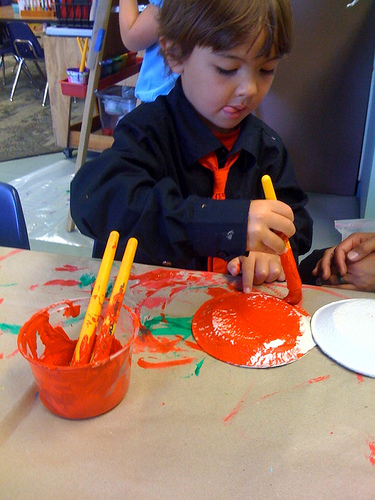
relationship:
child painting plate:
[69, 0, 314, 297] [191, 293, 316, 369]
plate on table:
[309, 296, 374, 381] [0, 245, 374, 498]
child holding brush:
[69, 0, 314, 297] [258, 173, 302, 299]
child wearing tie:
[69, 0, 314, 297] [198, 150, 241, 274]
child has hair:
[69, 0, 314, 297] [159, 0, 293, 81]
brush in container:
[73, 36, 89, 71] [67, 66, 90, 83]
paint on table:
[18, 297, 139, 420] [0, 245, 374, 498]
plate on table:
[191, 293, 316, 369] [0, 245, 374, 498]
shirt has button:
[70, 76, 314, 268] [214, 249, 229, 260]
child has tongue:
[69, 0, 314, 297] [222, 104, 236, 116]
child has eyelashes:
[69, 0, 314, 297] [214, 64, 238, 75]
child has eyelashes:
[69, 0, 314, 297] [260, 68, 276, 76]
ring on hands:
[336, 272, 346, 285] [312, 231, 374, 294]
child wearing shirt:
[69, 0, 314, 297] [208, 128, 242, 149]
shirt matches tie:
[208, 128, 242, 149] [198, 150, 241, 274]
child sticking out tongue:
[69, 0, 314, 297] [222, 104, 236, 116]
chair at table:
[0, 179, 30, 248] [0, 245, 374, 498]